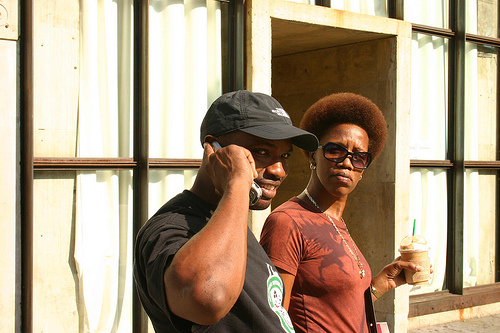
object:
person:
[131, 89, 319, 333]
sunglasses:
[317, 142, 372, 170]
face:
[315, 124, 369, 197]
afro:
[258, 89, 432, 333]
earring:
[310, 163, 317, 170]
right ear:
[299, 144, 319, 167]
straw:
[413, 219, 417, 238]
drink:
[397, 235, 429, 286]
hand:
[379, 255, 434, 290]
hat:
[199, 89, 319, 152]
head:
[203, 132, 293, 210]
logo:
[271, 107, 291, 119]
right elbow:
[162, 257, 245, 325]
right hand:
[201, 143, 258, 195]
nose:
[265, 158, 285, 179]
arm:
[137, 179, 254, 325]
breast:
[301, 254, 359, 296]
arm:
[261, 216, 304, 308]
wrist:
[370, 284, 382, 298]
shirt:
[131, 188, 296, 333]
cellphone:
[200, 139, 265, 207]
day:
[0, 0, 500, 333]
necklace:
[302, 188, 365, 278]